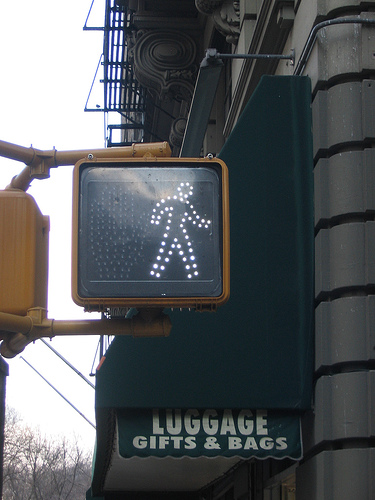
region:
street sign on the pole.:
[63, 148, 236, 309]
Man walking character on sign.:
[146, 174, 214, 284]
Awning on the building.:
[87, 66, 314, 496]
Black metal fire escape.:
[76, 0, 146, 143]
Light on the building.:
[173, 46, 225, 161]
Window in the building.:
[256, 470, 301, 496]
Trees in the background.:
[5, 407, 94, 498]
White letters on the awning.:
[122, 408, 294, 454]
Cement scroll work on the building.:
[126, 20, 204, 108]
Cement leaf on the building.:
[216, 1, 242, 27]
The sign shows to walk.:
[24, 133, 240, 333]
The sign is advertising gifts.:
[126, 399, 291, 481]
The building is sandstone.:
[253, 0, 374, 282]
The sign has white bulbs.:
[75, 167, 237, 288]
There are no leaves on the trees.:
[4, 431, 87, 492]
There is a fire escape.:
[72, 15, 154, 116]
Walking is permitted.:
[65, 146, 226, 299]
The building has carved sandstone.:
[93, 24, 235, 147]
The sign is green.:
[62, 386, 341, 468]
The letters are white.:
[106, 397, 367, 481]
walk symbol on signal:
[114, 164, 216, 287]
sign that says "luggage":
[131, 405, 283, 436]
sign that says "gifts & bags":
[130, 434, 297, 457]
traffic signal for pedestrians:
[47, 140, 249, 334]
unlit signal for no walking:
[84, 182, 143, 280]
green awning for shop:
[83, 344, 324, 480]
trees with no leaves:
[6, 413, 82, 493]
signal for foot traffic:
[32, 140, 267, 333]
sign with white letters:
[114, 393, 285, 465]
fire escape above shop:
[80, 9, 190, 137]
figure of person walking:
[152, 172, 227, 295]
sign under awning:
[141, 411, 284, 454]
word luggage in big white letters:
[144, 411, 269, 437]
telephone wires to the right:
[30, 344, 105, 437]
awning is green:
[125, 306, 299, 406]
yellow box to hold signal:
[0, 209, 73, 337]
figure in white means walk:
[145, 184, 211, 280]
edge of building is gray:
[318, 339, 371, 498]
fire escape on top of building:
[97, 0, 140, 107]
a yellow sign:
[6, 136, 224, 331]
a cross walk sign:
[79, 162, 226, 305]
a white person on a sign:
[146, 190, 211, 276]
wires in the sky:
[19, 346, 96, 417]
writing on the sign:
[108, 399, 303, 454]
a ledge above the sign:
[80, 9, 154, 121]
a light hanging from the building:
[177, 46, 302, 154]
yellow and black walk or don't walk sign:
[70, 156, 230, 304]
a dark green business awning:
[85, 74, 310, 498]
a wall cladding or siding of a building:
[292, 444, 374, 498]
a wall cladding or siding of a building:
[293, 376, 373, 456]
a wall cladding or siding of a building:
[297, 293, 373, 365]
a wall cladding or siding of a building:
[291, 212, 374, 304]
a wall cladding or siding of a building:
[291, 150, 369, 218]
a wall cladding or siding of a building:
[297, 88, 370, 150]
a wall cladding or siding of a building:
[290, 23, 374, 102]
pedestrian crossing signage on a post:
[63, 158, 237, 306]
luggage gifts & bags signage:
[105, 411, 305, 471]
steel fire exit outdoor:
[81, 1, 154, 146]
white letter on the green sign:
[150, 409, 165, 435]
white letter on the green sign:
[165, 405, 180, 432]